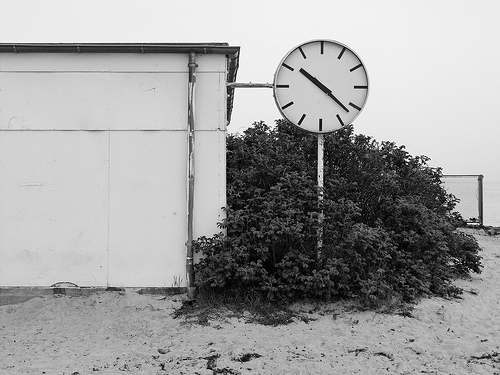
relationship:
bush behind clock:
[188, 121, 476, 306] [269, 38, 372, 139]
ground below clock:
[2, 285, 498, 372] [269, 38, 372, 139]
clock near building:
[269, 38, 372, 139] [1, 35, 273, 284]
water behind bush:
[453, 186, 498, 229] [188, 121, 482, 309]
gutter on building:
[0, 35, 243, 69] [1, 35, 273, 284]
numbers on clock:
[287, 54, 359, 115] [269, 38, 372, 139]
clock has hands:
[269, 38, 372, 139] [296, 63, 352, 114]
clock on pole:
[269, 38, 372, 139] [309, 133, 327, 277]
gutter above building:
[0, 35, 243, 69] [1, 35, 273, 284]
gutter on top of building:
[0, 35, 243, 69] [1, 35, 273, 284]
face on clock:
[287, 57, 354, 122] [269, 38, 372, 139]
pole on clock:
[309, 133, 327, 277] [269, 38, 372, 139]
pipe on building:
[183, 52, 204, 300] [1, 35, 273, 284]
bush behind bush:
[188, 121, 482, 309] [188, 121, 476, 306]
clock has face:
[269, 38, 372, 139] [287, 57, 354, 122]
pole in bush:
[309, 133, 327, 277] [188, 121, 476, 306]